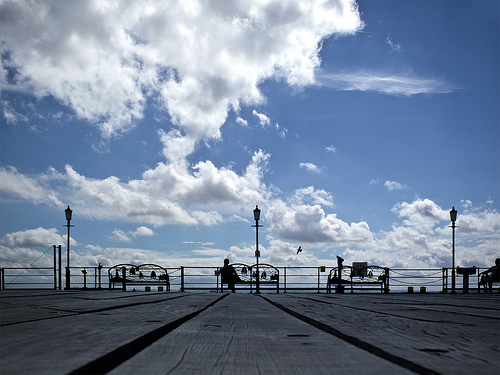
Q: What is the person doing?
A: Running.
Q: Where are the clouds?
A: In the sky.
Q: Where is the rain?
A: Nowhere.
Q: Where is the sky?
A: Background.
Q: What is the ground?
A: Asphalt.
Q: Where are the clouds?
A: Sky.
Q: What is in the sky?
A: Clouds.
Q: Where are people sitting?
A: Benches.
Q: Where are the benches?
A: Edge of a pier.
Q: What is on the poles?
A: Lights.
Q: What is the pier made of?
A: Wood.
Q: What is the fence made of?
A: Metal.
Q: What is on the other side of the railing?
A: Water.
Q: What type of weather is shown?
A: Partly cloudy.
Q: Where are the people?
A: Benches.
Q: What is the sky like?
A: Slightly cloudy.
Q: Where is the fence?
A: Background.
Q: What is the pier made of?
A: Wooden.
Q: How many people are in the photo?
A: One.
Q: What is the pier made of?
A: Wood.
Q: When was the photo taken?
A: Daytime.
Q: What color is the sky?
A: Blue.